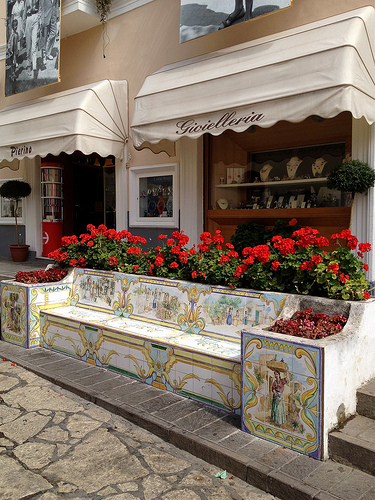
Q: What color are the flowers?
A: Red.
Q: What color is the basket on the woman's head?
A: Yellow.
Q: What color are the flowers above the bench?
A: Red.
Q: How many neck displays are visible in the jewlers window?
A: Three.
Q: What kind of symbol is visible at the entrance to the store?
A: An arrow.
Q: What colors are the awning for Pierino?
A: Tan and brown.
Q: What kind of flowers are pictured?
A: Geraniums.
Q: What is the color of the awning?
A: Light brown.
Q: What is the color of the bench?
A: White and brown.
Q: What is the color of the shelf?
A: Brown.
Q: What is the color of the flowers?
A: Red.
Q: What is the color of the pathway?
A: Grey.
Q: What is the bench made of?
A: Tiles.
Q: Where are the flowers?
A: Behind the bench.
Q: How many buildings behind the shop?
A: 2.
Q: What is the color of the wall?
A: Brown.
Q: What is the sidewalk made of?
A: The sidewalk is made of marble.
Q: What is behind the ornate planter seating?
A: There are red carnations.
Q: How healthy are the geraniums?
A: They are very healthy.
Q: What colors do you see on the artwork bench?
A: I see the colors yellow, blue, beige, ivory.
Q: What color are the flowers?
A: Red.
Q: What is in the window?
A: Jewelry.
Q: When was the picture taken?
A: Daytime.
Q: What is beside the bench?
A: Steps.